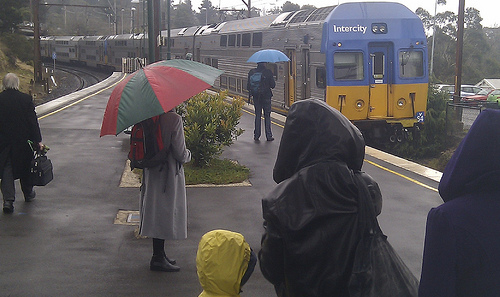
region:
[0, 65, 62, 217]
man wearing a black coat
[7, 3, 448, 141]
the train is blue, yellow and gray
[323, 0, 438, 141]
front of train is blue and yellow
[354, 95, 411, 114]
headlight in front the train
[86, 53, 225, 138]
A red and green umbrella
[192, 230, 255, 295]
A yellow hood on a raincoat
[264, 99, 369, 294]
A black jacket on a person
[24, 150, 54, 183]
A black bag in a man's hand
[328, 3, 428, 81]
A blue painted section on a train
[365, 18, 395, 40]
Lights on a train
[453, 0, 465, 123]
A telephone pole near a train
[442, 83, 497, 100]
Cars in a parking lot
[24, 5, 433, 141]
silver train with a blue and yellow front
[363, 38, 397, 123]
door on the front of a train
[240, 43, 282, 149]
person with a blue umbrella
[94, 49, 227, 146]
green and red umbrella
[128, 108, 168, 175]
red and grey backpack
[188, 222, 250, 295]
yellow rain jacket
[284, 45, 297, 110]
yellow door on the side of the train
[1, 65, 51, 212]
man in a black coat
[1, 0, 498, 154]
the train on the road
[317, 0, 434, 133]
the front of train is blue and yellow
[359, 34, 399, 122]
the door is yellow and blue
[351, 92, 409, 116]
the headlights on front the train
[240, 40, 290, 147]
man holding a blue umbrella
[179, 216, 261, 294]
the hood of a jacket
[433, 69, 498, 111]
cars on the parking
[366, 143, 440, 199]
white line on the platform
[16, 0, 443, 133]
the train is color gray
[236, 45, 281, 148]
man carrying a backpack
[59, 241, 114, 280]
the sidewalk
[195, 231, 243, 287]
a hood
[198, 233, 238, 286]
the hood is yellow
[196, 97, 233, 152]
a green plant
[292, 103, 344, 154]
a black hood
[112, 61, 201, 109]
an umbrella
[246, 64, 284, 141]
a person standing next to the train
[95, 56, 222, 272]
a woman standing under umbrella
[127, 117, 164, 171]
a red and black backpack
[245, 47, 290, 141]
a man standing under an umbrella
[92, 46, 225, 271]
woman holding an umbrella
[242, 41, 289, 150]
man has a blue umbrella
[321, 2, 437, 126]
the front of the train is blue and yellow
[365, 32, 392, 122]
door on a train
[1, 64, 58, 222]
man has gray hair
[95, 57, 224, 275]
person holding red and green umbrella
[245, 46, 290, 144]
person holding blue umbrella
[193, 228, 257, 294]
person wearing yellow raincoat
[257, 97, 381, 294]
person wearing black raincoat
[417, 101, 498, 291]
person wearing blue cloak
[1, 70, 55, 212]
person carrying black briefcase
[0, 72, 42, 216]
person wearing black coat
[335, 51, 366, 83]
window in front of train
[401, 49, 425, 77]
window in front of train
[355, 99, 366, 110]
headlight in front of train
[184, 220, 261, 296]
kid wears a yellow hood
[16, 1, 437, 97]
the cars of train are gray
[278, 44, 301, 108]
the side door of train is yellow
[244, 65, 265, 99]
teh backpack is blue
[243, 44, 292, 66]
teh umbrella is blue